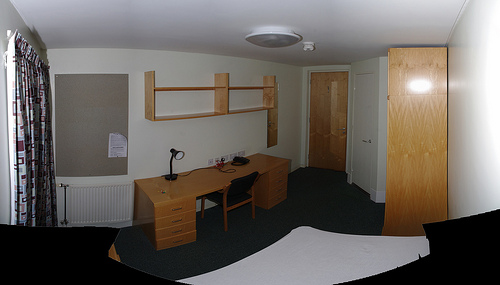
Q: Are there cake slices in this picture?
A: No, there are no cake slices.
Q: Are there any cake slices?
A: No, there are no cake slices.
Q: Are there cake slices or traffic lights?
A: No, there are no cake slices or traffic lights.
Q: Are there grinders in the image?
A: No, there are no grinders.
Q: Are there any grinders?
A: No, there are no grinders.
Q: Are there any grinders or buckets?
A: No, there are no grinders or buckets.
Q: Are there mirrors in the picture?
A: No, there are no mirrors.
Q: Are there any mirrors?
A: No, there are no mirrors.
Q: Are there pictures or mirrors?
A: No, there are no mirrors or pictures.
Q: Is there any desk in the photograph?
A: Yes, there is a desk.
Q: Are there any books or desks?
A: Yes, there is a desk.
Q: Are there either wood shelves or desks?
A: Yes, there is a wood desk.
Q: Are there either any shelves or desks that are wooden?
A: Yes, the desk is wooden.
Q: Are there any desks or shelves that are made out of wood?
A: Yes, the desk is made of wood.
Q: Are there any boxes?
A: No, there are no boxes.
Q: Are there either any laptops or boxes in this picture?
A: No, there are no boxes or laptops.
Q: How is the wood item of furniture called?
A: The piece of furniture is a desk.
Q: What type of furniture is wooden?
A: The furniture is a desk.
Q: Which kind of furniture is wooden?
A: The furniture is a desk.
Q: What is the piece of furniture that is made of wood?
A: The piece of furniture is a desk.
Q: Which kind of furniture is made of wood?
A: The furniture is a desk.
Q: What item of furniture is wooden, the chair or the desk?
A: The desk is wooden.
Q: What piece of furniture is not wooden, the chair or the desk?
A: The chair is not wooden.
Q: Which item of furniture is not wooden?
A: The piece of furniture is a chair.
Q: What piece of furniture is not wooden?
A: The piece of furniture is a chair.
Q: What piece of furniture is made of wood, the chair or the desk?
A: The desk is made of wood.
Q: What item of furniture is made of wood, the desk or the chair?
A: The desk is made of wood.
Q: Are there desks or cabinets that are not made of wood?
A: No, there is a desk but it is made of wood.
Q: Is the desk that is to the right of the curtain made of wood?
A: Yes, the desk is made of wood.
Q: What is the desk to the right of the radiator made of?
A: The desk is made of wood.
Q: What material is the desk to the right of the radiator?
A: The desk is made of wood.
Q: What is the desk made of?
A: The desk is made of wood.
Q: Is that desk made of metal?
A: No, the desk is made of wood.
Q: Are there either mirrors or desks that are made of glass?
A: No, there is a desk but it is made of wood.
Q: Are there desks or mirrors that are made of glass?
A: No, there is a desk but it is made of wood.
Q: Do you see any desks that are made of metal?
A: No, there is a desk but it is made of wood.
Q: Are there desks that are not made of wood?
A: No, there is a desk but it is made of wood.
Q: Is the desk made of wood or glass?
A: The desk is made of wood.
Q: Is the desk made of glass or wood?
A: The desk is made of wood.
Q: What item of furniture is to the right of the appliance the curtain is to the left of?
A: The piece of furniture is a desk.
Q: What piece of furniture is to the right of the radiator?
A: The piece of furniture is a desk.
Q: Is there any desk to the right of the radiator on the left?
A: Yes, there is a desk to the right of the radiator.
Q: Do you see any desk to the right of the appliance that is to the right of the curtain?
A: Yes, there is a desk to the right of the radiator.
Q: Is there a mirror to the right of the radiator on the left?
A: No, there is a desk to the right of the radiator.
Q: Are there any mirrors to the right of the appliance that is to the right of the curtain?
A: No, there is a desk to the right of the radiator.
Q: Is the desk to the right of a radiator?
A: Yes, the desk is to the right of a radiator.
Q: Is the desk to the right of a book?
A: No, the desk is to the right of a radiator.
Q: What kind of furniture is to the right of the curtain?
A: The piece of furniture is a desk.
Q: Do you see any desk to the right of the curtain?
A: Yes, there is a desk to the right of the curtain.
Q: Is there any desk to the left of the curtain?
A: No, the desk is to the right of the curtain.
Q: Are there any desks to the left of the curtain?
A: No, the desk is to the right of the curtain.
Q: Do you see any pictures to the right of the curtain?
A: No, there is a desk to the right of the curtain.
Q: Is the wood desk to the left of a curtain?
A: No, the desk is to the right of a curtain.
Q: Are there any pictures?
A: No, there are no pictures.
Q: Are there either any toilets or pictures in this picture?
A: No, there are no pictures or toilets.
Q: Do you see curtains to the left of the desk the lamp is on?
A: Yes, there is a curtain to the left of the desk.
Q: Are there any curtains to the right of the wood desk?
A: No, the curtain is to the left of the desk.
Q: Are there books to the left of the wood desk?
A: No, there is a curtain to the left of the desk.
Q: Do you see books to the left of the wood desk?
A: No, there is a curtain to the left of the desk.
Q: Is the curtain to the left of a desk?
A: Yes, the curtain is to the left of a desk.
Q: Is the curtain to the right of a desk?
A: No, the curtain is to the left of a desk.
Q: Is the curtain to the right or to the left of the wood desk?
A: The curtain is to the left of the desk.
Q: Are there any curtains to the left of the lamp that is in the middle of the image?
A: Yes, there is a curtain to the left of the lamp.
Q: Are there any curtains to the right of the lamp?
A: No, the curtain is to the left of the lamp.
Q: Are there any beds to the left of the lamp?
A: No, there is a curtain to the left of the lamp.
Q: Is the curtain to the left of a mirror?
A: No, the curtain is to the left of a lamp.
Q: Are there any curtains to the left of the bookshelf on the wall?
A: Yes, there is a curtain to the left of the bookshelf.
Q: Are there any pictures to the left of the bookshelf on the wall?
A: No, there is a curtain to the left of the bookshelf.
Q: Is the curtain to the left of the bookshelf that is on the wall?
A: Yes, the curtain is to the left of the bookshelf.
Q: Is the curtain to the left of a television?
A: No, the curtain is to the left of the bookshelf.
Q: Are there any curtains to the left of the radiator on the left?
A: Yes, there is a curtain to the left of the radiator.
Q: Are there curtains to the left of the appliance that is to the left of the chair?
A: Yes, there is a curtain to the left of the radiator.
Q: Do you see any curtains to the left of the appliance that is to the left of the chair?
A: Yes, there is a curtain to the left of the radiator.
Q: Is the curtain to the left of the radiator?
A: Yes, the curtain is to the left of the radiator.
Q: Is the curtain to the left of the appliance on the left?
A: Yes, the curtain is to the left of the radiator.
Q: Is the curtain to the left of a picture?
A: No, the curtain is to the left of the radiator.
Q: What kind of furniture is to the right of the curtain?
A: The piece of furniture is a bookshelf.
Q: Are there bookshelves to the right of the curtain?
A: Yes, there is a bookshelf to the right of the curtain.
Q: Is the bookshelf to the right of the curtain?
A: Yes, the bookshelf is to the right of the curtain.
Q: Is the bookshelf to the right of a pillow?
A: No, the bookshelf is to the right of the curtain.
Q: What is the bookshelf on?
A: The bookshelf is on the wall.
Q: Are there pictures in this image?
A: No, there are no pictures.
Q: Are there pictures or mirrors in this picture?
A: No, there are no pictures or mirrors.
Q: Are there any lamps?
A: Yes, there is a lamp.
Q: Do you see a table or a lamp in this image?
A: Yes, there is a lamp.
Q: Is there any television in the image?
A: No, there are no televisions.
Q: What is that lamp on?
A: The lamp is on the desk.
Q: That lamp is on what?
A: The lamp is on the desk.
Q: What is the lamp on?
A: The lamp is on the desk.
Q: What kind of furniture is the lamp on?
A: The lamp is on the desk.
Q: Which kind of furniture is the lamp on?
A: The lamp is on the desk.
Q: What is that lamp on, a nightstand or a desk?
A: The lamp is on a desk.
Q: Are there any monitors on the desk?
A: No, there is a lamp on the desk.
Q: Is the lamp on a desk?
A: Yes, the lamp is on a desk.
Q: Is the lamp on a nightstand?
A: No, the lamp is on a desk.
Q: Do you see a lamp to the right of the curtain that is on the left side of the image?
A: Yes, there is a lamp to the right of the curtain.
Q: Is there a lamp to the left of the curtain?
A: No, the lamp is to the right of the curtain.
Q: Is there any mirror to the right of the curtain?
A: No, there is a lamp to the right of the curtain.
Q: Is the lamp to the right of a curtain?
A: Yes, the lamp is to the right of a curtain.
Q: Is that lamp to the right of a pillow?
A: No, the lamp is to the right of a curtain.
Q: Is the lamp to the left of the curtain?
A: No, the lamp is to the right of the curtain.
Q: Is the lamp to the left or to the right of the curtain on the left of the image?
A: The lamp is to the right of the curtain.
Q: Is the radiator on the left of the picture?
A: Yes, the radiator is on the left of the image.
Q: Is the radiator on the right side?
A: No, the radiator is on the left of the image.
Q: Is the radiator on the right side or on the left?
A: The radiator is on the left of the image.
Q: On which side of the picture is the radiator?
A: The radiator is on the left of the image.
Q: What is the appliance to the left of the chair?
A: The appliance is a radiator.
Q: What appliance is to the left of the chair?
A: The appliance is a radiator.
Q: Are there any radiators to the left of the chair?
A: Yes, there is a radiator to the left of the chair.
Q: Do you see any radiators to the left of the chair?
A: Yes, there is a radiator to the left of the chair.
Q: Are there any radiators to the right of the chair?
A: No, the radiator is to the left of the chair.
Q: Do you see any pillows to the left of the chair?
A: No, there is a radiator to the left of the chair.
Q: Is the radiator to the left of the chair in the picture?
A: Yes, the radiator is to the left of the chair.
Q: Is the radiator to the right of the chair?
A: No, the radiator is to the left of the chair.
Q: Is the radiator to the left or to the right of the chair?
A: The radiator is to the left of the chair.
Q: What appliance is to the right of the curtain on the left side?
A: The appliance is a radiator.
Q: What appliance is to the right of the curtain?
A: The appliance is a radiator.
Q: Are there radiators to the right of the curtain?
A: Yes, there is a radiator to the right of the curtain.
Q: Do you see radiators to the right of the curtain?
A: Yes, there is a radiator to the right of the curtain.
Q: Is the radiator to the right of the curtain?
A: Yes, the radiator is to the right of the curtain.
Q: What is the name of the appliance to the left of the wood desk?
A: The appliance is a radiator.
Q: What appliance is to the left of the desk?
A: The appliance is a radiator.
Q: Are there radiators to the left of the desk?
A: Yes, there is a radiator to the left of the desk.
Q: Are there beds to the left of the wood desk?
A: No, there is a radiator to the left of the desk.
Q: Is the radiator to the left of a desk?
A: Yes, the radiator is to the left of a desk.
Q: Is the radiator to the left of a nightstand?
A: No, the radiator is to the left of a desk.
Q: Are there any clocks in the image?
A: No, there are no clocks.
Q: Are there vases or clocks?
A: No, there are no clocks or vases.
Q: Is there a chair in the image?
A: Yes, there is a chair.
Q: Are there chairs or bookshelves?
A: Yes, there is a chair.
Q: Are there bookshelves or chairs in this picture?
A: Yes, there is a chair.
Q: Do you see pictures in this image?
A: No, there are no pictures.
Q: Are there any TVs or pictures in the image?
A: No, there are no pictures or tvs.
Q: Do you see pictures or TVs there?
A: No, there are no pictures or tvs.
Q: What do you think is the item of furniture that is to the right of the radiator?
A: The piece of furniture is a chair.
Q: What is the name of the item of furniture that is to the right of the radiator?
A: The piece of furniture is a chair.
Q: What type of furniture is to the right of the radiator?
A: The piece of furniture is a chair.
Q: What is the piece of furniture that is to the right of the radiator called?
A: The piece of furniture is a chair.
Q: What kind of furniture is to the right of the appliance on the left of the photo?
A: The piece of furniture is a chair.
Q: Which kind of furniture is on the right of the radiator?
A: The piece of furniture is a chair.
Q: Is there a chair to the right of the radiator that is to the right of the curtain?
A: Yes, there is a chair to the right of the radiator.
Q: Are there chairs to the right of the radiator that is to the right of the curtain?
A: Yes, there is a chair to the right of the radiator.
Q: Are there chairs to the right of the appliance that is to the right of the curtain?
A: Yes, there is a chair to the right of the radiator.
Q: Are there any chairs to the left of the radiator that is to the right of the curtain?
A: No, the chair is to the right of the radiator.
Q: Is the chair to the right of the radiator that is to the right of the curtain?
A: Yes, the chair is to the right of the radiator.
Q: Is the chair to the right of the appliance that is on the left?
A: Yes, the chair is to the right of the radiator.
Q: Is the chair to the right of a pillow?
A: No, the chair is to the right of the radiator.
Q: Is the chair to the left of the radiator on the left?
A: No, the chair is to the right of the radiator.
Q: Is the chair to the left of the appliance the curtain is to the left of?
A: No, the chair is to the right of the radiator.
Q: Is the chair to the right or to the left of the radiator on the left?
A: The chair is to the right of the radiator.